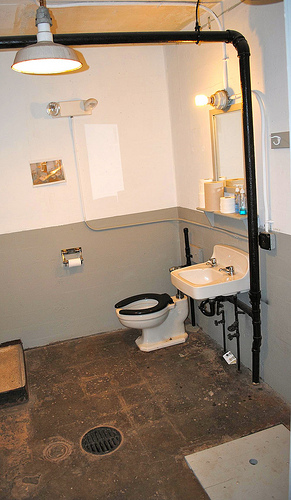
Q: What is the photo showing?
A: It is showing a bathroom.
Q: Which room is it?
A: It is a bathroom.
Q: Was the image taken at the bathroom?
A: Yes, it was taken in the bathroom.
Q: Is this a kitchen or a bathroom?
A: It is a bathroom.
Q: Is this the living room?
A: No, it is the bathroom.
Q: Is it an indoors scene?
A: Yes, it is indoors.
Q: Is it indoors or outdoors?
A: It is indoors.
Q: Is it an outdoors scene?
A: No, it is indoors.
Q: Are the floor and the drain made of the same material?
A: No, the floor is made of cement and the drain is made of metal.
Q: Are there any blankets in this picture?
A: No, there are no blankets.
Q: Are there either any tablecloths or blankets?
A: No, there are no blankets or tablecloths.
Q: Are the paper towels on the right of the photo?
A: Yes, the paper towels are on the right of the image.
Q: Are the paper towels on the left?
A: No, the paper towels are on the right of the image.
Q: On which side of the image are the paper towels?
A: The paper towels are on the right of the image.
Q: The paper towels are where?
A: The paper towels are in the bathroom.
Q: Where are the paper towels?
A: The paper towels are in the bathroom.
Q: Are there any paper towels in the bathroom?
A: Yes, there are paper towels in the bathroom.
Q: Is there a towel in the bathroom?
A: No, there are paper towels in the bathroom.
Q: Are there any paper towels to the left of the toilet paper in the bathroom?
A: Yes, there are paper towels to the left of the toilet paper.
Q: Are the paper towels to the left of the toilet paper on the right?
A: Yes, the paper towels are to the left of the toilet paper.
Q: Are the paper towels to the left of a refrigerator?
A: No, the paper towels are to the left of the toilet paper.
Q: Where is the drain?
A: The drain is on the floor.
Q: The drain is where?
A: The drain is in the bathroom.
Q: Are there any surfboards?
A: No, there are no surfboards.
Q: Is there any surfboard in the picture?
A: No, there are no surfboards.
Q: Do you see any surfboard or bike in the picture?
A: No, there are no surfboards or bikes.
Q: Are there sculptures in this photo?
A: No, there are no sculptures.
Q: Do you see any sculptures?
A: No, there are no sculptures.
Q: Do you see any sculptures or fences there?
A: No, there are no sculptures or fences.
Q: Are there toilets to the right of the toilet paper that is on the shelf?
A: Yes, there is a toilet to the right of the toilet paper.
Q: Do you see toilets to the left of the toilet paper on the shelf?
A: No, the toilet is to the right of the toilet paper.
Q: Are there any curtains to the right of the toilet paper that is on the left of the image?
A: No, there is a toilet to the right of the toilet paper.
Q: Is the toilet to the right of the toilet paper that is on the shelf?
A: Yes, the toilet is to the right of the toilet paper.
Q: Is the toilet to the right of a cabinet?
A: No, the toilet is to the right of the toilet paper.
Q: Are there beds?
A: No, there are no beds.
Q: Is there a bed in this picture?
A: No, there are no beds.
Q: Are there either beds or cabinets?
A: No, there are no beds or cabinets.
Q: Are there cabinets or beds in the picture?
A: No, there are no beds or cabinets.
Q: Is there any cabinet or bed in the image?
A: No, there are no beds or cabinets.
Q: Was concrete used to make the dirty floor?
A: Yes, the floor is made of concrete.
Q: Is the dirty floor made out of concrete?
A: Yes, the floor is made of concrete.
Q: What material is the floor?
A: The floor is made of concrete.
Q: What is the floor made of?
A: The floor is made of concrete.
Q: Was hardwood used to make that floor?
A: No, the floor is made of concrete.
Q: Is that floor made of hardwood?
A: No, the floor is made of concrete.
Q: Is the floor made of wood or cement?
A: The floor is made of cement.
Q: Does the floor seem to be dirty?
A: Yes, the floor is dirty.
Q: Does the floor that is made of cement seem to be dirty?
A: Yes, the floor is dirty.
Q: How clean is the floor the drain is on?
A: The floor is dirty.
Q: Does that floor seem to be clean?
A: No, the floor is dirty.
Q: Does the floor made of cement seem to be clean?
A: No, the floor is dirty.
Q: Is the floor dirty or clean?
A: The floor is dirty.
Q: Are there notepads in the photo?
A: No, there are no notepads.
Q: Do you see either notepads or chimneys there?
A: No, there are no notepads or chimneys.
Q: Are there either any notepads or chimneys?
A: No, there are no notepads or chimneys.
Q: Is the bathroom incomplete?
A: Yes, the bathroom is incomplete.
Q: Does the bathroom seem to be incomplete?
A: Yes, the bathroom is incomplete.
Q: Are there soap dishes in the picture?
A: No, there are no soap dishes.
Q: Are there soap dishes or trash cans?
A: No, there are no soap dishes or trash cans.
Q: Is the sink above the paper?
A: Yes, the sink is above the paper.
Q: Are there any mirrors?
A: Yes, there is a mirror.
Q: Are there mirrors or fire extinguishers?
A: Yes, there is a mirror.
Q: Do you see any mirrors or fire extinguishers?
A: Yes, there is a mirror.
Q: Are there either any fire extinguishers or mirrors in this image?
A: Yes, there is a mirror.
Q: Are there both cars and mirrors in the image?
A: No, there is a mirror but no cars.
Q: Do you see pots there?
A: No, there are no pots.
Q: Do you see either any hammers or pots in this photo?
A: No, there are no pots or hammers.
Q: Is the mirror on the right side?
A: Yes, the mirror is on the right of the image.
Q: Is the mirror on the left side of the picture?
A: No, the mirror is on the right of the image.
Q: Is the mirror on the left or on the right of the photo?
A: The mirror is on the right of the image.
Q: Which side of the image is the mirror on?
A: The mirror is on the right of the image.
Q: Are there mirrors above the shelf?
A: Yes, there is a mirror above the shelf.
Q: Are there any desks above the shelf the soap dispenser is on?
A: No, there is a mirror above the shelf.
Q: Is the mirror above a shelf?
A: Yes, the mirror is above a shelf.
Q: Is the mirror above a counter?
A: No, the mirror is above a shelf.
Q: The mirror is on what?
A: The mirror is on the wall.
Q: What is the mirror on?
A: The mirror is on the wall.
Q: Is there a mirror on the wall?
A: Yes, there is a mirror on the wall.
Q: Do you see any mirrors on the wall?
A: Yes, there is a mirror on the wall.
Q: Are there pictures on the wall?
A: No, there is a mirror on the wall.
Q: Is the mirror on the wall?
A: Yes, the mirror is on the wall.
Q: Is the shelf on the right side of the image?
A: Yes, the shelf is on the right of the image.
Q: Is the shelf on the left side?
A: No, the shelf is on the right of the image.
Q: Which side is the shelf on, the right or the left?
A: The shelf is on the right of the image.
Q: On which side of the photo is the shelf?
A: The shelf is on the right of the image.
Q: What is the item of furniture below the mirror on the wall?
A: The piece of furniture is a shelf.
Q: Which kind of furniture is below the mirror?
A: The piece of furniture is a shelf.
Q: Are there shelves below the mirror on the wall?
A: Yes, there is a shelf below the mirror.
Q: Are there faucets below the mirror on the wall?
A: No, there is a shelf below the mirror.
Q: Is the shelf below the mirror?
A: Yes, the shelf is below the mirror.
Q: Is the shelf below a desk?
A: No, the shelf is below the mirror.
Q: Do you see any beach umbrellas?
A: No, there are no beach umbrellas.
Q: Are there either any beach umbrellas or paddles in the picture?
A: No, there are no beach umbrellas or paddles.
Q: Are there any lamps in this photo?
A: Yes, there is a lamp.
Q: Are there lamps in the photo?
A: Yes, there is a lamp.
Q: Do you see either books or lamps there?
A: Yes, there is a lamp.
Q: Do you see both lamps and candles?
A: No, there is a lamp but no candles.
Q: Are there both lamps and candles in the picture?
A: No, there is a lamp but no candles.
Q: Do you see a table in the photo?
A: No, there are no tables.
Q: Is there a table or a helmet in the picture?
A: No, there are no tables or helmets.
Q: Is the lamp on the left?
A: Yes, the lamp is on the left of the image.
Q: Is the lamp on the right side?
A: No, the lamp is on the left of the image.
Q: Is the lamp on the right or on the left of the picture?
A: The lamp is on the left of the image.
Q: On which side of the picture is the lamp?
A: The lamp is on the left of the image.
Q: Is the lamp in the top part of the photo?
A: Yes, the lamp is in the top of the image.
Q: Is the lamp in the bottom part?
A: No, the lamp is in the top of the image.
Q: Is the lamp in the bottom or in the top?
A: The lamp is in the top of the image.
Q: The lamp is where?
A: The lamp is in the bathroom.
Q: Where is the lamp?
A: The lamp is in the bathroom.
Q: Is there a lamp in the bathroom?
A: Yes, there is a lamp in the bathroom.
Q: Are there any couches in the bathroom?
A: No, there is a lamp in the bathroom.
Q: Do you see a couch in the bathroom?
A: No, there is a lamp in the bathroom.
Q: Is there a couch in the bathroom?
A: No, there is a lamp in the bathroom.